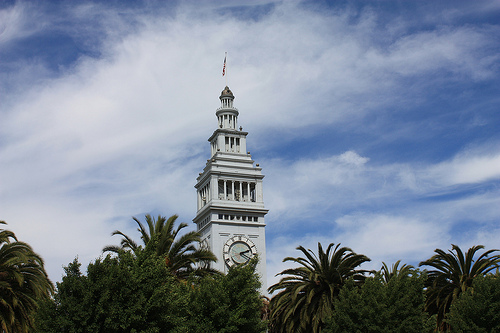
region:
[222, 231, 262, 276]
clock on the side of a building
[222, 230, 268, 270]
clock on the side of a building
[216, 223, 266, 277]
clock on the side of a building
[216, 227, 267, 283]
clock on the side of a building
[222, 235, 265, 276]
clock on the side of a building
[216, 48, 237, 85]
American flag on top of the building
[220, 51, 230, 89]
American flag on top of the building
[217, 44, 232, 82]
American flag on top of the building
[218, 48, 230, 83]
American flag on top of the building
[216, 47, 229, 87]
American flag on top of the building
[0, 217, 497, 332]
row of trees on bottom of picture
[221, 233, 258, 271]
clock on tower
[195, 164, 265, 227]
bell portion of clock tower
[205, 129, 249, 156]
third tier down on tower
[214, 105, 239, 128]
second tier down on tower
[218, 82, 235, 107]
first tier on clock tower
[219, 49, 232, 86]
american flag on tower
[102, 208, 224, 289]
top of second palm tree from right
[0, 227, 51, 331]
green tree by steeple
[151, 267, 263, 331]
green tree by steeple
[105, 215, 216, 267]
green tree by steeple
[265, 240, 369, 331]
green tree by steeple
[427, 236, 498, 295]
green tree by steeple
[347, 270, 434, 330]
green tree by steeple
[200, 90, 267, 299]
tall white steeple in sky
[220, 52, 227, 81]
US flag on steeple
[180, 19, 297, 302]
A clock tower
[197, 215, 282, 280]
This is a clock face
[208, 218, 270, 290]
The clock face is round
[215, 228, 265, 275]
The numbers are in roman numerals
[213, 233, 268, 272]
The time is about 2:20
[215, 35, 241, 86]
There is a flag at the top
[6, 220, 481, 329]
Trees in front of the tower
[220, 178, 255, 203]
Four white pillars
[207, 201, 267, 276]
a building with a clock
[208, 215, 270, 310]
a building with a large clock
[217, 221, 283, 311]
a building with an outside clock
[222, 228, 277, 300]
a building with a large outside clock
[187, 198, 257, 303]
a large clock on a building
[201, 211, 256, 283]
an outside clock on a building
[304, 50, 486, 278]
a blue sky with clouds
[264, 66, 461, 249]
a sky that is blue